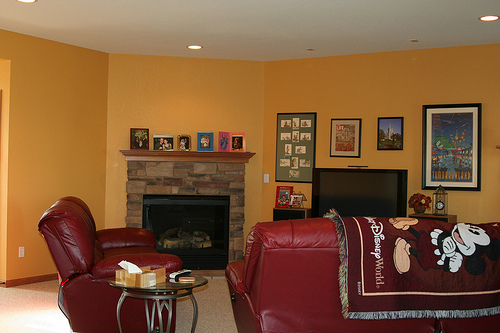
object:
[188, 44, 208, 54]
light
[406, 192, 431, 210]
flowers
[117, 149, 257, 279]
firepace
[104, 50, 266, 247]
wall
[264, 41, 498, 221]
wall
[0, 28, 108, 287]
wall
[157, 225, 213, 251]
logs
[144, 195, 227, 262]
fireplace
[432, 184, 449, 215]
birdcage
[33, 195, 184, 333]
chair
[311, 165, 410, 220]
television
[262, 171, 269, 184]
lightswitch